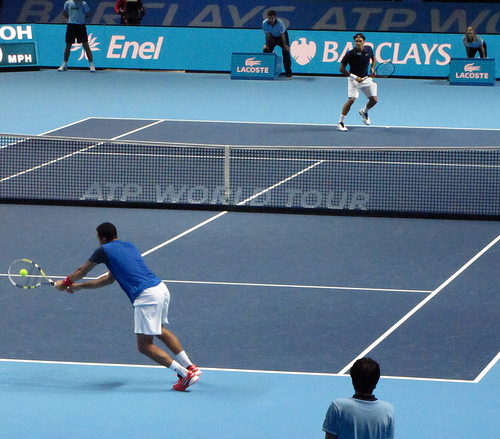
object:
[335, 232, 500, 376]
line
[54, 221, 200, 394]
player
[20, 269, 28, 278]
ball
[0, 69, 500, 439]
court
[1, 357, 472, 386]
line